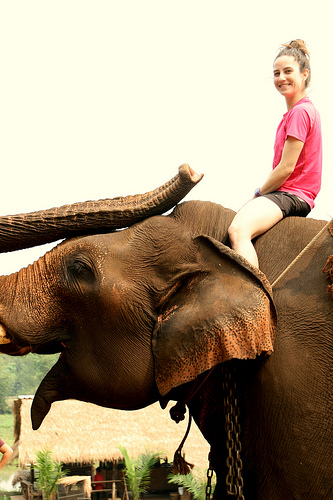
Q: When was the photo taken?
A: Daytime.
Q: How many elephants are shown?
A: One.